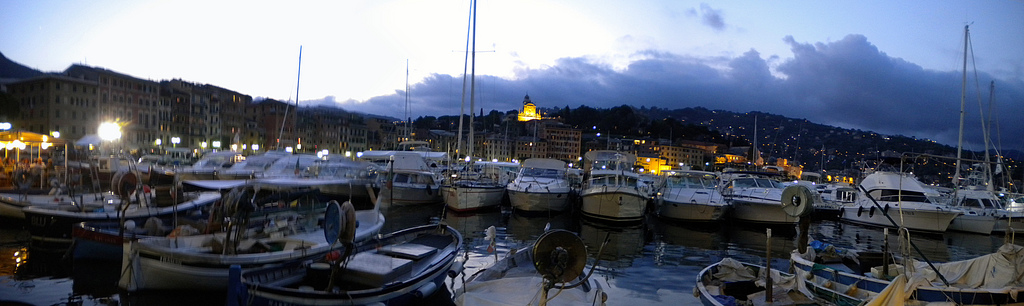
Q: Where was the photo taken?
A: At a marina.